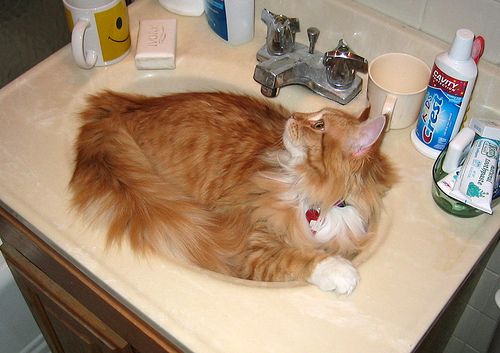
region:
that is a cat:
[90, 56, 409, 290]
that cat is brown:
[88, 105, 368, 267]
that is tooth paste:
[413, 30, 475, 149]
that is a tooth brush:
[472, 34, 487, 58]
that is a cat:
[372, 58, 421, 121]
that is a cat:
[66, 0, 125, 77]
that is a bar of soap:
[443, 130, 478, 157]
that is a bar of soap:
[126, 15, 175, 66]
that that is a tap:
[256, 11, 306, 64]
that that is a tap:
[328, 30, 365, 105]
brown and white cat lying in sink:
[66, 86, 403, 304]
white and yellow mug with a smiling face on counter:
[57, 0, 135, 72]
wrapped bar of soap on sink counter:
[131, 10, 181, 73]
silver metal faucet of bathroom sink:
[243, 5, 370, 104]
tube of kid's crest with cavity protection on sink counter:
[406, 23, 482, 167]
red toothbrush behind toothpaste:
[473, 33, 485, 68]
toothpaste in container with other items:
[450, 126, 496, 221]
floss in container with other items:
[467, 114, 499, 142]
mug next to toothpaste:
[361, 46, 431, 136]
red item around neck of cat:
[301, 208, 322, 225]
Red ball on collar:
[287, 191, 333, 242]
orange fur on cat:
[175, 124, 230, 165]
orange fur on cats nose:
[283, 104, 311, 134]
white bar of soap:
[138, 37, 178, 66]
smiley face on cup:
[105, 12, 133, 56]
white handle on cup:
[63, 26, 98, 71]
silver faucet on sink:
[248, 60, 288, 100]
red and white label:
[431, 66, 464, 97]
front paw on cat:
[308, 262, 363, 290]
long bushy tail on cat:
[71, 138, 231, 277]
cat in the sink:
[68, 43, 390, 350]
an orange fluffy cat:
[55, 72, 384, 312]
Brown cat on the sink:
[69, 88, 401, 301]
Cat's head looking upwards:
[282, 103, 392, 180]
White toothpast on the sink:
[409, 26, 479, 165]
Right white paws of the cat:
[305, 253, 362, 295]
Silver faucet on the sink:
[253, 6, 373, 108]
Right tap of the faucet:
[319, 36, 369, 91]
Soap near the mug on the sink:
[132, 17, 179, 71]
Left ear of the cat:
[354, 113, 391, 155]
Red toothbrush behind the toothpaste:
[472, 35, 484, 66]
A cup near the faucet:
[362, 49, 431, 132]